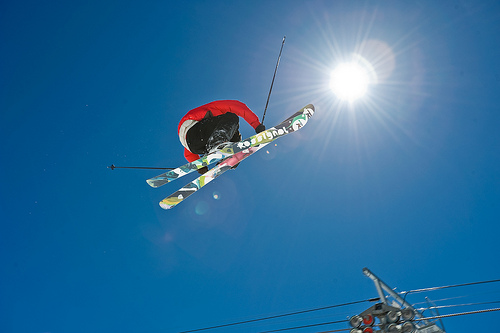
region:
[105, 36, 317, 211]
skier jumping high in the air into the sun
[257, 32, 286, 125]
ski poles in skier hand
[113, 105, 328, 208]
bottom of ski of the skier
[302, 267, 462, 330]
ski tram device for skiers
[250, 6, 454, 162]
the sun and its rays in blue sky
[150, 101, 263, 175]
skier in red jacketon skis in air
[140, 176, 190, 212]
tip of back of both skis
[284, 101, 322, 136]
tip of front of both skis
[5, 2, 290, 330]
blue sky all around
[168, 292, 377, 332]
wire for tram that take skiers to top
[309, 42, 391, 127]
The bright sun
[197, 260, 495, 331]
An empty ski lift cable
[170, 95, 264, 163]
A jumping skiier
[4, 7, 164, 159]
A clear, blue sky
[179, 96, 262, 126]
A red winter jacket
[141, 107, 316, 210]
Skiis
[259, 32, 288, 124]
A black and white ski pole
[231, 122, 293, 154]
A white text label on the skiis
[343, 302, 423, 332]
A pulley system for the ski lift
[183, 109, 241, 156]
A pair of black snow pants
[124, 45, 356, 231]
person wears red coat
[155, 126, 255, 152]
person wears black pants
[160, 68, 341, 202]
person wears multicolor skis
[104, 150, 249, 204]
two black ski poles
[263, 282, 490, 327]
black cable beneath skier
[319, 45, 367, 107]
sun shines brightly in sky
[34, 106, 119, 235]
sky is blue and cloudless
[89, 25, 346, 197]
ski poles are extended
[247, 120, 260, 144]
person wears black gloves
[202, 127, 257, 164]
person wears black shoes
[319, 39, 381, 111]
the bright sun in the sky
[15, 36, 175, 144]
sky is clear and blue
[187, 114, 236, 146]
skier's pants are black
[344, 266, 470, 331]
part of ski lift on the bottom right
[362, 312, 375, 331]
two orange wheels of the ski lift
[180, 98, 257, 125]
the skier's jacket is orange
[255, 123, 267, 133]
skier's glove is black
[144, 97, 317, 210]
skier up in the air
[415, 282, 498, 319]
ski lift wires are made of metal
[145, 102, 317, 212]
the bottom of the skis are multi colored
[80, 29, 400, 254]
a man is skiing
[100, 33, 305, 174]
the man is holding ski poles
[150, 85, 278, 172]
the man is wearing a red coat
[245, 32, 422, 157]
the sun is bright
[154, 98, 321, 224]
the skis are multi colored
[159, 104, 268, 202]
the pants are black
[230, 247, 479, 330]
wires under the skier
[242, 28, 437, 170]
the sun has rays coming from it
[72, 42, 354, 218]
the skier is making a jump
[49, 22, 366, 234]
the skier jumped high